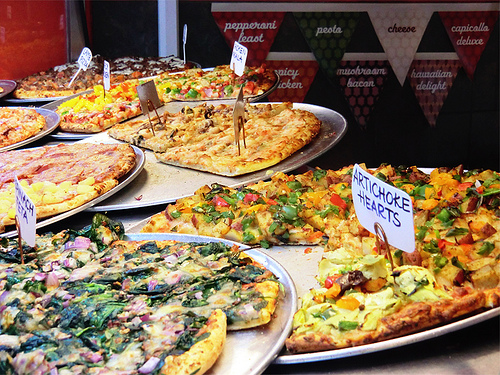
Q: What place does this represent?
A: It represents the display.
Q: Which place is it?
A: It is a display.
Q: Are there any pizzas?
A: Yes, there is a pizza.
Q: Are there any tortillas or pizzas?
A: Yes, there is a pizza.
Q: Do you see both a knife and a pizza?
A: No, there is a pizza but no knives.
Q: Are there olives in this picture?
A: No, there are no olives.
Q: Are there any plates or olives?
A: No, there are no olives or plates.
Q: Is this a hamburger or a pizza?
A: This is a pizza.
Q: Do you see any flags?
A: Yes, there is a flag.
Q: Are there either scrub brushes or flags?
A: Yes, there is a flag.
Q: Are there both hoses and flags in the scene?
A: No, there is a flag but no hoses.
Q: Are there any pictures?
A: No, there are no pictures.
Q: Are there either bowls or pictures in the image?
A: No, there are no pictures or bowls.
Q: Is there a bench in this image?
A: No, there are no benches.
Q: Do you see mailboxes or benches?
A: No, there are no benches or mailboxes.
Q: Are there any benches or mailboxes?
A: No, there are no benches or mailboxes.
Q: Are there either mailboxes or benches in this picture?
A: No, there are no benches or mailboxes.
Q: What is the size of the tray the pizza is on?
A: The tray is large.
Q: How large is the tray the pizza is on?
A: The tray is large.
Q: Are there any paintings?
A: No, there are no paintings.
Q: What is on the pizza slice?
A: The toppings are on the pizza slice.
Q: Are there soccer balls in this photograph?
A: No, there are no soccer balls.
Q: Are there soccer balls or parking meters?
A: No, there are no soccer balls or parking meters.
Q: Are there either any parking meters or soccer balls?
A: No, there are no soccer balls or parking meters.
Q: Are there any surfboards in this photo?
A: No, there are no surfboards.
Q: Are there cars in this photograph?
A: No, there are no cars.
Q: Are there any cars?
A: No, there are no cars.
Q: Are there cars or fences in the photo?
A: No, there are no cars or fences.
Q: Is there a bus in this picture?
A: No, there are no buses.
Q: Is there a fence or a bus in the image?
A: No, there are no buses or fences.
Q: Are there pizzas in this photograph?
A: Yes, there is a pizza.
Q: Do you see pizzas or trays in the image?
A: Yes, there is a pizza.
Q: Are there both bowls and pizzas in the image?
A: No, there is a pizza but no bowls.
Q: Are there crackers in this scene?
A: No, there are no crackers.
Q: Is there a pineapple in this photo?
A: Yes, there is a pineapple.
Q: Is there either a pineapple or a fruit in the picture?
A: Yes, there is a pineapple.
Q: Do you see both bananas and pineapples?
A: No, there is a pineapple but no bananas.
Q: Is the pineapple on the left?
A: Yes, the pineapple is on the left of the image.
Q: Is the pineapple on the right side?
A: No, the pineapple is on the left of the image.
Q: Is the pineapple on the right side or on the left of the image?
A: The pineapple is on the left of the image.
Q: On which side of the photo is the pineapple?
A: The pineapple is on the left of the image.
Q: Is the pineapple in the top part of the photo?
A: Yes, the pineapple is in the top of the image.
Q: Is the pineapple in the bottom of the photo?
A: No, the pineapple is in the top of the image.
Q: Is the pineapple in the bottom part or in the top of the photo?
A: The pineapple is in the top of the image.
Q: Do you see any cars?
A: No, there are no cars.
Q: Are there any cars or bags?
A: No, there are no cars or bags.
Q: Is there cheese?
A: Yes, there is cheese.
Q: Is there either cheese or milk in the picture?
A: Yes, there is cheese.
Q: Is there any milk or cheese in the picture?
A: Yes, there is cheese.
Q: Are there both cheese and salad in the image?
A: No, there is cheese but no salad.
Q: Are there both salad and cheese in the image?
A: No, there is cheese but no salad.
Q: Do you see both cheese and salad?
A: No, there is cheese but no salad.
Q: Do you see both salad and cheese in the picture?
A: No, there is cheese but no salad.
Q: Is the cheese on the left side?
A: Yes, the cheese is on the left of the image.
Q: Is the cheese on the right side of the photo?
A: No, the cheese is on the left of the image.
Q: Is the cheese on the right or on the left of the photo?
A: The cheese is on the left of the image.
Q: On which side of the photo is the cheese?
A: The cheese is on the left of the image.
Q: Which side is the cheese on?
A: The cheese is on the left of the image.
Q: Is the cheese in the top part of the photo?
A: Yes, the cheese is in the top of the image.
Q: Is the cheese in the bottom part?
A: No, the cheese is in the top of the image.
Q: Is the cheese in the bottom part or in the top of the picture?
A: The cheese is in the top of the image.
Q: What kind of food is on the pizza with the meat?
A: The food is cheese.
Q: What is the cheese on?
A: The cheese is on the pizza.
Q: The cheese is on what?
A: The cheese is on the pizza.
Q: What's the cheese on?
A: The cheese is on the pizza.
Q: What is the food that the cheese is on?
A: The food is a pizza.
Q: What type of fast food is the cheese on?
A: The cheese is on the pizza.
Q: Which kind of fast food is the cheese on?
A: The cheese is on the pizza.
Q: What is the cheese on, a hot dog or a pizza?
A: The cheese is on a pizza.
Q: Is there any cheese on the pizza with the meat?
A: Yes, there is cheese on the pizza.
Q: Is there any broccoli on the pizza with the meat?
A: No, there is cheese on the pizza.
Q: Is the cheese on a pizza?
A: Yes, the cheese is on a pizza.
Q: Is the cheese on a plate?
A: No, the cheese is on a pizza.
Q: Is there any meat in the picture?
A: Yes, there is meat.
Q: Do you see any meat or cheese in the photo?
A: Yes, there is meat.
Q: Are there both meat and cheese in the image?
A: Yes, there are both meat and cheese.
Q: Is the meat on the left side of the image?
A: Yes, the meat is on the left of the image.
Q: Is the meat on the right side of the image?
A: No, the meat is on the left of the image.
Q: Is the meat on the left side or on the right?
A: The meat is on the left of the image.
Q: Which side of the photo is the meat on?
A: The meat is on the left of the image.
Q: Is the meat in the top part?
A: Yes, the meat is in the top of the image.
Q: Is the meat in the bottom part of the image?
A: No, the meat is in the top of the image.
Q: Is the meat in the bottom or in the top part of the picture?
A: The meat is in the top of the image.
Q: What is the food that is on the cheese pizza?
A: The food is meat.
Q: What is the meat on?
A: The meat is on the pizza.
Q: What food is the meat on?
A: The meat is on the pizza.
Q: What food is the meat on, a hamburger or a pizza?
A: The meat is on a pizza.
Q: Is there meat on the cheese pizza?
A: Yes, there is meat on the pizza.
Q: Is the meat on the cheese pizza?
A: Yes, the meat is on the pizza.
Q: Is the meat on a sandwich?
A: No, the meat is on the pizza.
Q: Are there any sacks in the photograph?
A: No, there are no sacks.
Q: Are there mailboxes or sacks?
A: No, there are no sacks or mailboxes.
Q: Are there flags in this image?
A: Yes, there is a flag.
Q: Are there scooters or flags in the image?
A: Yes, there is a flag.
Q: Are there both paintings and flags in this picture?
A: No, there is a flag but no paintings.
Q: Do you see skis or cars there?
A: No, there are no cars or skis.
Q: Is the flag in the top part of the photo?
A: Yes, the flag is in the top of the image.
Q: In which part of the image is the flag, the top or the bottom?
A: The flag is in the top of the image.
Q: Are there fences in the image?
A: No, there are no fences.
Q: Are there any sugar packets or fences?
A: No, there are no fences or sugar packets.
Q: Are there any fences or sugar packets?
A: No, there are no fences or sugar packets.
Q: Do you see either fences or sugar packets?
A: No, there are no fences or sugar packets.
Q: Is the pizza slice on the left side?
A: Yes, the pizza slice is on the left of the image.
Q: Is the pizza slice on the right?
A: No, the pizza slice is on the left of the image.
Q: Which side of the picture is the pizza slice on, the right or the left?
A: The pizza slice is on the left of the image.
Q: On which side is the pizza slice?
A: The pizza slice is on the left of the image.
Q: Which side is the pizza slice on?
A: The pizza slice is on the left of the image.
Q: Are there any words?
A: Yes, there are words.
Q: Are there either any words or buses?
A: Yes, there are words.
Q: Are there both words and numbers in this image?
A: No, there are words but no numbers.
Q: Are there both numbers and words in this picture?
A: No, there are words but no numbers.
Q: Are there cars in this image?
A: No, there are no cars.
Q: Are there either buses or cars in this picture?
A: No, there are no cars or buses.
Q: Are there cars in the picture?
A: No, there are no cars.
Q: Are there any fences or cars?
A: No, there are no cars or fences.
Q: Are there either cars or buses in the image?
A: No, there are no cars or buses.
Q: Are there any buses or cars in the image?
A: No, there are no cars or buses.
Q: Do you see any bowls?
A: No, there are no bowls.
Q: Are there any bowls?
A: No, there are no bowls.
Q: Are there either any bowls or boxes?
A: No, there are no bowls or boxes.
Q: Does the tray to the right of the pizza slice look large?
A: Yes, the tray is large.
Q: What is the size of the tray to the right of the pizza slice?
A: The tray is large.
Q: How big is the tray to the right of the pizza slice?
A: The tray is large.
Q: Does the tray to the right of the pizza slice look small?
A: No, the tray is large.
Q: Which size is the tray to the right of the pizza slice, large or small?
A: The tray is large.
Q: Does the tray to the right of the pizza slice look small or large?
A: The tray is large.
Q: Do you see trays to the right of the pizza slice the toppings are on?
A: Yes, there is a tray to the right of the pizza slice.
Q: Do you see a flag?
A: Yes, there is a flag.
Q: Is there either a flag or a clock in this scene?
A: Yes, there is a flag.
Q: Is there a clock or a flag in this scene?
A: Yes, there is a flag.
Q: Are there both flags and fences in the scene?
A: No, there is a flag but no fences.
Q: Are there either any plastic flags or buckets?
A: Yes, there is a plastic flag.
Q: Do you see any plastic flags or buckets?
A: Yes, there is a plastic flag.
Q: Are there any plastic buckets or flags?
A: Yes, there is a plastic flag.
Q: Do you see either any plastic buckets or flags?
A: Yes, there is a plastic flag.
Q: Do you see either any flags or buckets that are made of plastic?
A: Yes, the flag is made of plastic.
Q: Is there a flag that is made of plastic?
A: Yes, there is a flag that is made of plastic.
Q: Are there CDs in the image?
A: No, there are no cds.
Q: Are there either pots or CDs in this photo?
A: No, there are no CDs or pots.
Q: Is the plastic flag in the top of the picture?
A: Yes, the flag is in the top of the image.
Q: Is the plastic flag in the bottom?
A: No, the flag is in the top of the image.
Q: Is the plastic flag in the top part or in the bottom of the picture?
A: The flag is in the top of the image.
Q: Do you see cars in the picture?
A: No, there are no cars.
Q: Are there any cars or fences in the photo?
A: No, there are no cars or fences.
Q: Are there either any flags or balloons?
A: Yes, there is a flag.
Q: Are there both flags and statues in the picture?
A: No, there is a flag but no statues.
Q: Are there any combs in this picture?
A: No, there are no combs.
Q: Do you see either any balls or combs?
A: No, there are no combs or balls.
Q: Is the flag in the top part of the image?
A: Yes, the flag is in the top of the image.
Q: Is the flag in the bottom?
A: No, the flag is in the top of the image.